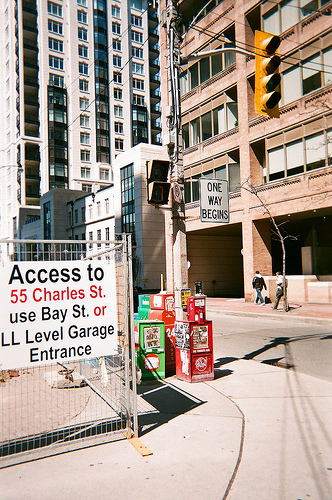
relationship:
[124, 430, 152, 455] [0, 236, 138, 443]
plank under fence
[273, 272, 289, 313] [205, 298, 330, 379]
man walking down street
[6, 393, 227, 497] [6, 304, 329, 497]
cement slab on ground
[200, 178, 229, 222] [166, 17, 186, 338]
sign on pole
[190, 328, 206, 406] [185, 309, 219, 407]
metal newspaper box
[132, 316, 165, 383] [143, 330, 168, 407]
green metal newspaper box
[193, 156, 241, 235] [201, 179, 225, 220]
white and black street sign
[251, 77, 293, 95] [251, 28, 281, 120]
yellow electric stop light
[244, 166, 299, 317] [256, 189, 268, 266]
tree with no leaves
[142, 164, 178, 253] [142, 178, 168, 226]
walk and dont walk box